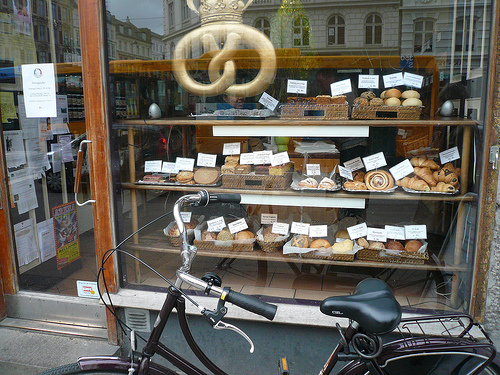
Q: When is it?
A: Day time.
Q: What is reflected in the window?
A: A pretzel.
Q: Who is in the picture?
A: No one.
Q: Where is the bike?
A: In front of the window.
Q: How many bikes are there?
A: One.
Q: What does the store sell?
A: Baked goods.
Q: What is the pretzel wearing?
A: A crown.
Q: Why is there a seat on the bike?
A: So the rider can sit down.